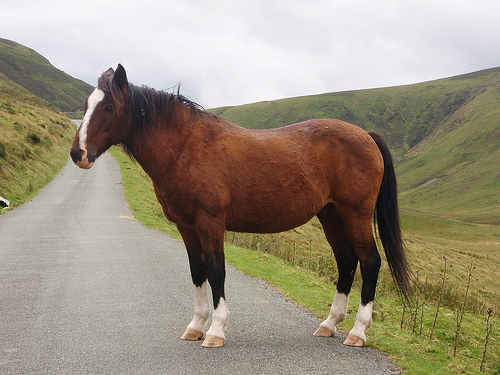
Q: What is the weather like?
A: It is cloudy.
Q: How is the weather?
A: It is cloudy.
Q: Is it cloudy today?
A: Yes, it is cloudy.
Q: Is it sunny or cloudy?
A: It is cloudy.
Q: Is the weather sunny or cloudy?
A: It is cloudy.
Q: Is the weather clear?
A: No, it is cloudy.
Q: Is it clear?
A: No, it is cloudy.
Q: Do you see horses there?
A: Yes, there is a horse.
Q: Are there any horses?
A: Yes, there is a horse.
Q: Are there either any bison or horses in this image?
A: Yes, there is a horse.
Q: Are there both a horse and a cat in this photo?
A: No, there is a horse but no cats.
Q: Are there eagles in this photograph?
A: No, there are no eagles.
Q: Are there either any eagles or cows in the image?
A: No, there are no eagles or cows.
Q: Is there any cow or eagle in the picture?
A: No, there are no eagles or cows.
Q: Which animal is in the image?
A: The animal is a horse.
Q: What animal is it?
A: The animal is a horse.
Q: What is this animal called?
A: This is a horse.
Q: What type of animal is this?
A: This is a horse.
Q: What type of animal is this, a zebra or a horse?
A: This is a horse.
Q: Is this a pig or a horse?
A: This is a horse.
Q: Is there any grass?
A: Yes, there is grass.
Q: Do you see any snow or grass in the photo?
A: Yes, there is grass.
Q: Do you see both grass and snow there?
A: No, there is grass but no snow.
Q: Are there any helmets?
A: No, there are no helmets.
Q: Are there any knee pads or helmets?
A: No, there are no helmets or knee pads.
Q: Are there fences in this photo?
A: Yes, there is a fence.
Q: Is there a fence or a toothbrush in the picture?
A: Yes, there is a fence.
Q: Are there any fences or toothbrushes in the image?
A: Yes, there is a fence.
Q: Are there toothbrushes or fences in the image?
A: Yes, there is a fence.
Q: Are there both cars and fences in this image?
A: No, there is a fence but no cars.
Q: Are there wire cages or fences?
A: Yes, there is a wire fence.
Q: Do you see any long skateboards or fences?
A: Yes, there is a long fence.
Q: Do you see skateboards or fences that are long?
A: Yes, the fence is long.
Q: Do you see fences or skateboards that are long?
A: Yes, the fence is long.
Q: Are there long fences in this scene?
A: Yes, there is a long fence.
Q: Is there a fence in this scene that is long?
A: Yes, there is a fence that is long.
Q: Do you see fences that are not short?
A: Yes, there is a long fence.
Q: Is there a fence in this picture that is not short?
A: Yes, there is a long fence.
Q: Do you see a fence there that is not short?
A: Yes, there is a long fence.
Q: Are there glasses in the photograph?
A: No, there are no glasses.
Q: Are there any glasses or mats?
A: No, there are no glasses or mats.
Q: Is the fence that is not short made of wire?
A: Yes, the fence is made of wire.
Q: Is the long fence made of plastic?
A: No, the fence is made of wire.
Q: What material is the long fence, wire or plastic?
A: The fence is made of wire.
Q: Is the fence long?
A: Yes, the fence is long.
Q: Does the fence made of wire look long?
A: Yes, the fence is long.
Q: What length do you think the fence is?
A: The fence is long.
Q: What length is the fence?
A: The fence is long.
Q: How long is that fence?
A: The fence is long.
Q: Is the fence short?
A: No, the fence is long.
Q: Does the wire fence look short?
A: No, the fence is long.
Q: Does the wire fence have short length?
A: No, the fence is long.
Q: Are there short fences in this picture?
A: No, there is a fence but it is long.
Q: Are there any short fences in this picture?
A: No, there is a fence but it is long.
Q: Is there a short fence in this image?
A: No, there is a fence but it is long.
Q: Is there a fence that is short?
A: No, there is a fence but it is long.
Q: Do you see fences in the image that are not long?
A: No, there is a fence but it is long.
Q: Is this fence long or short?
A: The fence is long.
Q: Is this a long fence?
A: Yes, this is a long fence.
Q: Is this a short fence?
A: No, this is a long fence.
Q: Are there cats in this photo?
A: No, there are no cats.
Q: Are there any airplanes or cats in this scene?
A: No, there are no cats or airplanes.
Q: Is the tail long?
A: Yes, the tail is long.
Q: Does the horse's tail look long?
A: Yes, the tail is long.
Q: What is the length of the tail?
A: The tail is long.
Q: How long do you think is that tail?
A: The tail is long.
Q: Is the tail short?
A: No, the tail is long.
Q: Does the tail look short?
A: No, the tail is long.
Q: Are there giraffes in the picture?
A: No, there are no giraffes.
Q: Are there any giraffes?
A: No, there are no giraffes.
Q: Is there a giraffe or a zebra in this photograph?
A: No, there are no giraffes or zebras.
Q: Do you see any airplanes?
A: No, there are no airplanes.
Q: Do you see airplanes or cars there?
A: No, there are no airplanes or cars.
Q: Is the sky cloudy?
A: Yes, the sky is cloudy.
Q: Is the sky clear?
A: No, the sky is cloudy.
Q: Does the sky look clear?
A: No, the sky is cloudy.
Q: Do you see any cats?
A: No, there are no cats.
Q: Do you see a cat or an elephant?
A: No, there are no cats or elephants.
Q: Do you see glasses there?
A: No, there are no glasses.